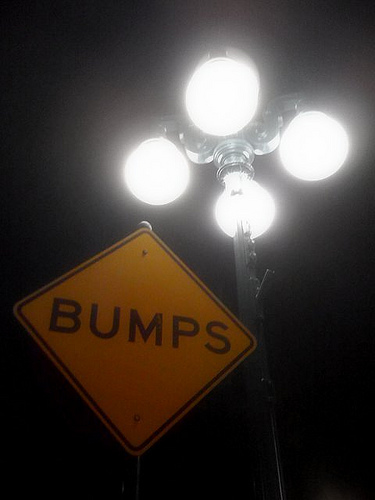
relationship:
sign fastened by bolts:
[13, 225, 257, 461] [125, 240, 154, 432]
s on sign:
[203, 319, 233, 355] [13, 225, 257, 453]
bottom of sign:
[90, 408, 183, 466] [13, 225, 257, 453]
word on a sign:
[46, 293, 234, 357] [23, 182, 272, 447]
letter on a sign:
[48, 295, 82, 336] [11, 219, 267, 466]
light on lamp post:
[275, 106, 357, 182] [162, 96, 291, 498]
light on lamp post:
[212, 168, 280, 236] [162, 96, 291, 498]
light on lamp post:
[181, 55, 264, 140] [162, 96, 291, 498]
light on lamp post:
[117, 136, 192, 208] [162, 96, 291, 498]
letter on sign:
[169, 313, 198, 349] [13, 225, 257, 453]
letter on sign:
[125, 306, 167, 346] [13, 225, 257, 453]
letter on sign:
[89, 299, 122, 339] [13, 225, 257, 453]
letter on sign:
[48, 295, 82, 333] [13, 225, 257, 453]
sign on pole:
[13, 225, 257, 453] [119, 448, 144, 498]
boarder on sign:
[12, 228, 256, 456] [18, 206, 269, 435]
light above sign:
[212, 168, 280, 236] [13, 188, 279, 466]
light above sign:
[275, 106, 349, 184] [13, 188, 279, 466]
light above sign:
[181, 55, 264, 140] [13, 188, 279, 466]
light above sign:
[117, 136, 192, 208] [13, 188, 279, 466]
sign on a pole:
[13, 225, 257, 453] [110, 450, 160, 498]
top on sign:
[137, 218, 152, 231] [13, 225, 257, 461]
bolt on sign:
[132, 412, 141, 421] [13, 225, 257, 453]